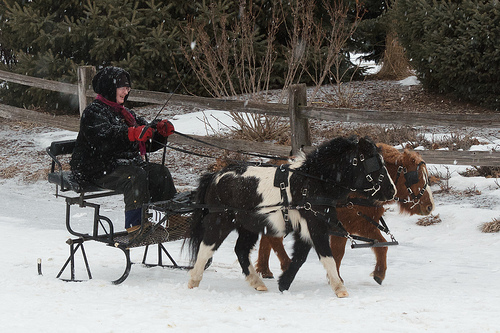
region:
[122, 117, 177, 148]
the gloves are red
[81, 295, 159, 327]
the snow is white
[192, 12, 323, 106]
the tree is brown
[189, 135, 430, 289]
the horses are walking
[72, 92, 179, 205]
the coat is black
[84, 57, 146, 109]
the hat is black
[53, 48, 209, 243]
the woman is white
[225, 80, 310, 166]
the fence is wooden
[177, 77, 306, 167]
the fence is brown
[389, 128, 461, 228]
the horse is red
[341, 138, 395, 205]
a black horse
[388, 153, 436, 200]
a brown horse's head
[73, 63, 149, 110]
old woman's face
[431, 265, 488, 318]
white snow on the ground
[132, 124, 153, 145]
red winter mittens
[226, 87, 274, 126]
a brown fence in the background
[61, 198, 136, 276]
the old woman's sleigh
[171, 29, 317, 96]
a brown branch in the background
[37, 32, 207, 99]
green tree's in the background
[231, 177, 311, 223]
a white spot on the black horse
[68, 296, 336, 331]
White snow covering the ground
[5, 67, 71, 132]
A wooden picket fence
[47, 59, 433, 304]
Two horses pulling a woman on a carriage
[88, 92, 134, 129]
A red scarf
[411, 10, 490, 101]
A green tree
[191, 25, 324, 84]
A dead tree in the winter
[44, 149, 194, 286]
a sled made of metal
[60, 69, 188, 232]
A woman riding a horse drawn carriage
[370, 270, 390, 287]
A horse hoof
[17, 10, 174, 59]
A green fern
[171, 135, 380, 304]
black and white miniature pony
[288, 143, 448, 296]
red miniature pony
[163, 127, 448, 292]
two ponies pulling a sleigh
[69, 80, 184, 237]
woman riding a sleigh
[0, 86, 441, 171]
brown wooden fence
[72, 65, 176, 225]
elderly woman wearing a winter hat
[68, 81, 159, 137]
woman wearing a red scarf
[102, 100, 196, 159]
woman wearing red gloves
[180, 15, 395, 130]
brown winter scrubs with no leafs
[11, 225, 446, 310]
beautiful snow covered road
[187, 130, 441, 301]
two ponies pulling sleigh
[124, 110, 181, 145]
red mittens on rider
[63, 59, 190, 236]
person on sleigh holding reigns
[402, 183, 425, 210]
bridle on pony's face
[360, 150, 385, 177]
blinder covering pony's eye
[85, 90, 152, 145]
cranberry colored scarf around neck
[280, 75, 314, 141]
worn wood fence post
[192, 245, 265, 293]
white legs on pony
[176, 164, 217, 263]
long black tail on pony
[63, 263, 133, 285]
blades on bottom of sleigh